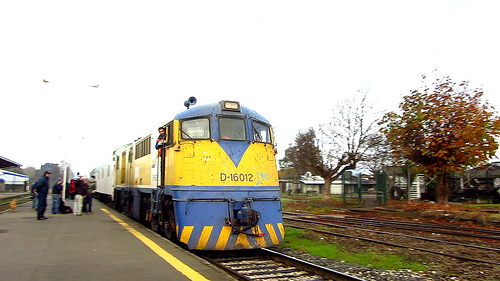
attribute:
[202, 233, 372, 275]
tracks — train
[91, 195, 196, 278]
strip — yellow, warning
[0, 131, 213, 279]
platform — train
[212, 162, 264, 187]
numbers — identification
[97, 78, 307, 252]
engine — train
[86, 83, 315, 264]
engine — train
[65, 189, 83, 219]
pants — white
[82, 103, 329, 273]
car — train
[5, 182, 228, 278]
platform — train, cement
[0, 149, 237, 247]
station — train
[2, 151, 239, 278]
station — train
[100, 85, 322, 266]
train — yellow, blue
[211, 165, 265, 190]
number — D-16012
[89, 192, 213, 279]
line — yellow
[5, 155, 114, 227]
people — group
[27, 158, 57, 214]
clothes — blue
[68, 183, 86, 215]
pants — white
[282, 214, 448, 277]
grass — patch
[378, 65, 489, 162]
leaves — dry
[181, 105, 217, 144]
windshield — small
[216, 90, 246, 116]
light — small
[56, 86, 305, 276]
train — large, blue, yellow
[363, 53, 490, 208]
trees — autumn, in right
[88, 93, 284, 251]
train — blue, yellow lined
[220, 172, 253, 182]
letters — black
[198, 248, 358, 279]
train tracks — black, rusty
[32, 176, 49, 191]
jacket — blue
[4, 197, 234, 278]
platform — caution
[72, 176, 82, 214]
man — white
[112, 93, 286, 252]
train locomotive — blue and yellow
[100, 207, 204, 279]
stripe — yellow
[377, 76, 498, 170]
leaves — yellow and red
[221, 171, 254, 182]
d-16012 — locomotive identifying number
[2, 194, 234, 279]
train platform — open air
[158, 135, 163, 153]
vest — orange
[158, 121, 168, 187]
engine window — side window